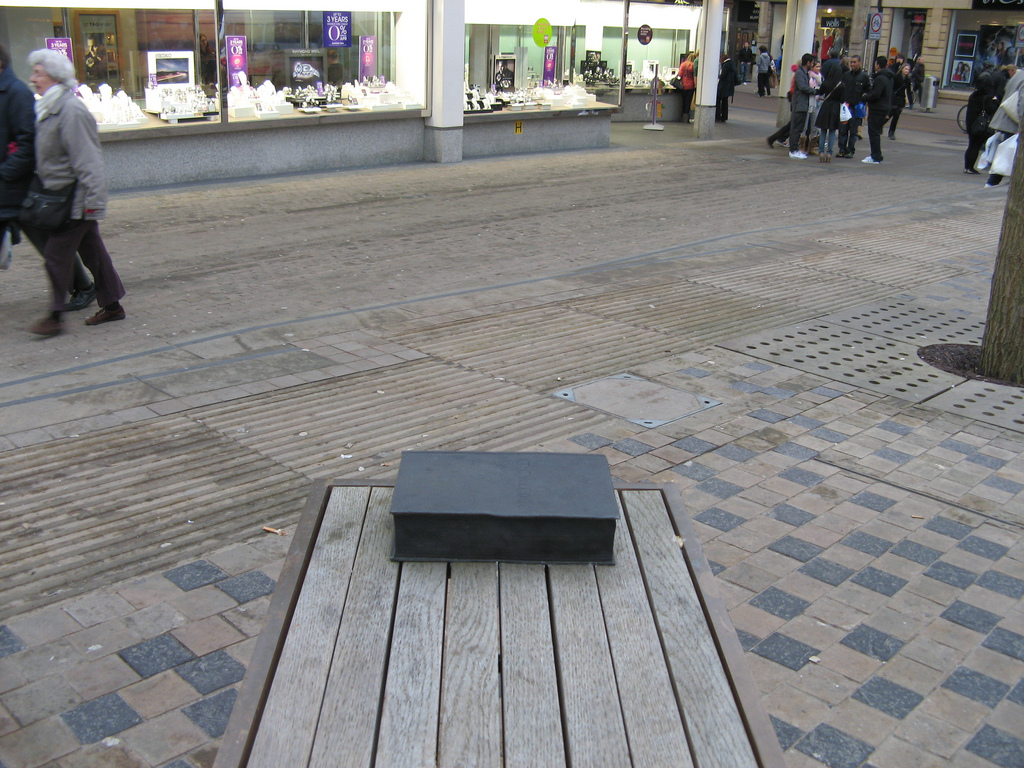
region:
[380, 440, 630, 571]
The black box at the end of the table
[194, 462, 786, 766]
The wood table with a black box on it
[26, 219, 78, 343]
The blurry leg of the woman in the grey coat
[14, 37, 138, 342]
The woman with a blurry left leg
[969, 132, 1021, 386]
The tree trunk that is partially visible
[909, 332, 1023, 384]
The circular planter the tree is growing in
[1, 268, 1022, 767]
The brick portions of the sidewalk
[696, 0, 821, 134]
The white and grey pillars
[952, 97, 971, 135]
The partially seen wheel of a bike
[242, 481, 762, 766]
a wooden plank secret door in the ground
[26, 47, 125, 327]
an old lady with grey hair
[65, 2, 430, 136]
a window in a shop near the pathway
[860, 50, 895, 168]
a man in black jeans and a white shoes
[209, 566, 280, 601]
a black stone in the ground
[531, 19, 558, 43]
a green sign on a window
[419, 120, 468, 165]
a cement pillar on the wall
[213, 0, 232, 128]
a metal divider in the window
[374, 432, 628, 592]
Black box on the top of table.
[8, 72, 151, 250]
Grey sweater on the man's body.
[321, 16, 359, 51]
Purple poster on the side of the window.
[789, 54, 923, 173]
Group of people shopping together.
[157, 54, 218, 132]
White framed picture by the glass.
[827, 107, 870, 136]
White bag in man's hands.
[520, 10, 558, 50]
Green poster on the glass.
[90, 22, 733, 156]
Glass building lit up on the side of the building.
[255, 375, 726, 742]
a dark brown bench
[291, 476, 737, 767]
a bench made of wood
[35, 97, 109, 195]
a woman in a gray coat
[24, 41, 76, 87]
a woman with white hair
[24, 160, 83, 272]
a woman walking with a black purse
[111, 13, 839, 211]
various retail stores